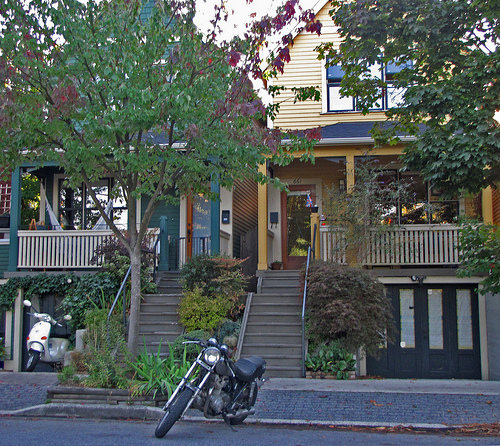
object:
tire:
[155, 383, 198, 438]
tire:
[23, 348, 38, 373]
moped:
[20, 299, 72, 373]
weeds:
[56, 365, 81, 387]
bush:
[299, 259, 397, 352]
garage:
[359, 275, 489, 384]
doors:
[449, 282, 482, 378]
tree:
[3, 0, 325, 368]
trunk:
[127, 257, 141, 382]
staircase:
[235, 268, 311, 379]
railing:
[16, 226, 162, 270]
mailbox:
[268, 209, 279, 231]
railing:
[301, 244, 313, 372]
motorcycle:
[153, 336, 272, 441]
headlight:
[203, 345, 221, 366]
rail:
[319, 225, 488, 268]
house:
[7, 2, 270, 276]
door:
[279, 182, 320, 270]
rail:
[106, 265, 132, 325]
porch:
[255, 149, 494, 271]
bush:
[178, 283, 233, 330]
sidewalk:
[0, 367, 500, 433]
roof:
[280, 120, 455, 146]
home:
[234, 1, 500, 381]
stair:
[248, 301, 305, 314]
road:
[0, 414, 500, 446]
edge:
[2, 398, 499, 435]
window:
[326, 80, 357, 114]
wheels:
[224, 381, 259, 427]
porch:
[8, 149, 219, 273]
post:
[255, 154, 270, 272]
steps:
[258, 284, 304, 296]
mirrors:
[21, 297, 37, 311]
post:
[209, 166, 221, 260]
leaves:
[219, 143, 244, 160]